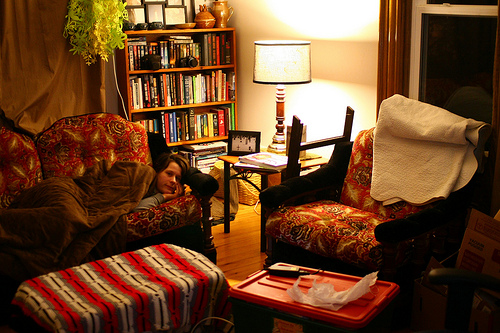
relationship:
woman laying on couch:
[0, 154, 188, 280] [3, 112, 218, 307]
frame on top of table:
[227, 130, 260, 159] [219, 150, 328, 234]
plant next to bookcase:
[62, 0, 131, 65] [116, 26, 238, 173]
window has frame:
[419, 13, 497, 125] [378, 0, 499, 148]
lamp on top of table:
[254, 39, 311, 151] [219, 150, 328, 234]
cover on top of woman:
[1, 160, 156, 316] [0, 154, 188, 280]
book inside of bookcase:
[209, 70, 216, 103] [116, 26, 238, 173]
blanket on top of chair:
[370, 93, 494, 205] [260, 126, 467, 332]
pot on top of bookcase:
[195, 4, 215, 29] [116, 26, 238, 173]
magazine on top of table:
[239, 149, 301, 169] [219, 150, 328, 234]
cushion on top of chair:
[263, 126, 429, 267] [260, 126, 467, 332]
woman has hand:
[0, 154, 188, 280] [161, 185, 184, 201]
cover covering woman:
[1, 160, 156, 316] [0, 154, 188, 280]